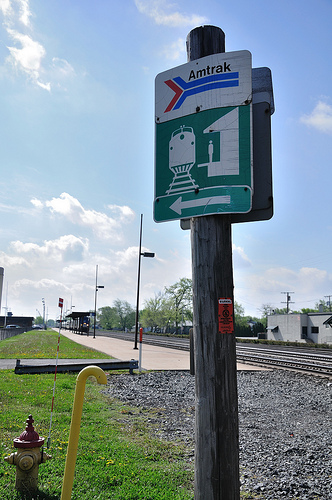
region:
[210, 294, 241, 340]
Red sign on post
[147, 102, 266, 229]
Green and white sign on post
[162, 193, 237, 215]
White arrow pointing left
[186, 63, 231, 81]
Black AMTRAK lettering on white sign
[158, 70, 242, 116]
Blue and red symbol on sign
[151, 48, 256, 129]
White sign on post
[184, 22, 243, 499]
Wooden post with signs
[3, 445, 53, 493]
Yellow bottom of fire hydrant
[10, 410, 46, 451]
Red top of fire hydrant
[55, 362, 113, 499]
Yellow pipe in ground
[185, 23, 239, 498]
a wooden signpost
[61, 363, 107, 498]
a curved yellow pole next to the signpost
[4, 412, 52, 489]
a small fire hydrant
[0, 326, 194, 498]
a strip of green grass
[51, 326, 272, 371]
a paved platform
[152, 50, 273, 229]
a metal sign attached to the post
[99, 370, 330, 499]
a gravel-covered area next to the tracks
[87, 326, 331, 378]
a set of train tracks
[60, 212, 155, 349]
a row of lamp posts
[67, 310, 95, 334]
a small shelter at the train stop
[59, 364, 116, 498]
Curved yellow pipe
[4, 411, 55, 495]
Red and yellow fire hydrant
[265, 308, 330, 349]
White one level building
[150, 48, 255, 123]
Amtrak train sign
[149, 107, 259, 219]
Sign indicating where the train platform is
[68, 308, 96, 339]
Shelter for those waiting for trains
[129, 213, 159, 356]
Black lamp post with square head.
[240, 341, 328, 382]
Two train tracks side by side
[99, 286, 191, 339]
Line of trees beginning to turn green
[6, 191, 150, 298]
White fluffy clouds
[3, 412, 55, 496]
a fire hydrant with red top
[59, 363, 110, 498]
a yellow crooked cane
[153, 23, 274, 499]
an Amtrack sign with wooden pole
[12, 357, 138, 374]
a metal barricade fence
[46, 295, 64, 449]
a red and white pole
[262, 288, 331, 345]
a white, blocky building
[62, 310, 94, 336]
a row of passenger shelters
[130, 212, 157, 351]
a tall street light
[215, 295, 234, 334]
a small red notice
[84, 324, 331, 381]
a length of train track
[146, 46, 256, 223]
Amtrak station signs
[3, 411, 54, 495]
Yellow and red fire hydrant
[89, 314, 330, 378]
Multiple sets of railroad tracks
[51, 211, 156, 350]
Long row of street lights currently turned off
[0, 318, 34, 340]
Concrete block in front of station parking lot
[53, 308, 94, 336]
Train station waiting areas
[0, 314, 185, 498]
Small grassy field decoration with yellow dandelions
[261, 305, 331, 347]
Short concrete building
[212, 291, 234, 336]
Orange tag for pole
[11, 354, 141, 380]
Metal roadside rail gaurd